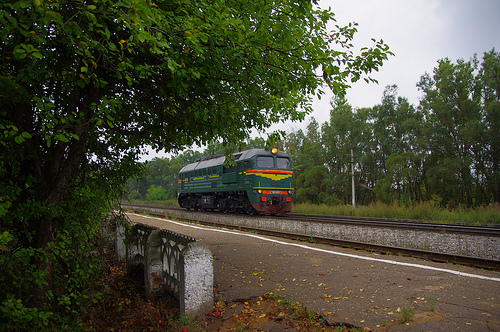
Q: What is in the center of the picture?
A: Train.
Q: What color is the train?
A: Green.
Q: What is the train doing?
A: Driving.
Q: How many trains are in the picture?
A: One.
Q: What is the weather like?
A: Sunny.